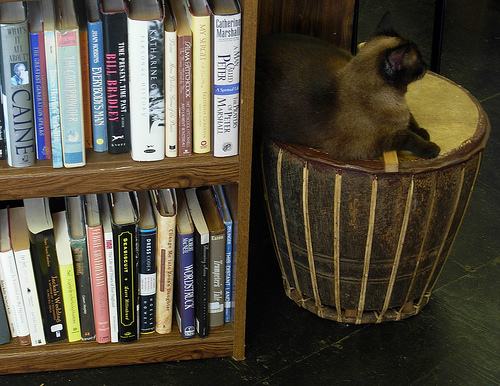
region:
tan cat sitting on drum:
[257, 13, 442, 160]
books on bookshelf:
[3, 1, 238, 166]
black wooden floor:
[257, 186, 498, 384]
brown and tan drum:
[261, 69, 490, 326]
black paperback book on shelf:
[22, 195, 67, 349]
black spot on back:
[305, 73, 345, 120]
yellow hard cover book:
[191, 7, 214, 158]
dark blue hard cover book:
[172, 211, 196, 345]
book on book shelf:
[211, 3, 236, 157]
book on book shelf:
[196, 188, 224, 328]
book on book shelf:
[175, 207, 197, 339]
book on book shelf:
[151, 189, 175, 332]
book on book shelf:
[136, 192, 156, 334]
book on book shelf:
[107, 190, 139, 342]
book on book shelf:
[97, 195, 119, 345]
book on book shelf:
[83, 196, 108, 342]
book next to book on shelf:
[210, 1, 241, 157]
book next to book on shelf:
[188, 0, 214, 156]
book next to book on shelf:
[9, 202, 45, 345]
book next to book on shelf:
[21, 196, 68, 342]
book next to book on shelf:
[54, 209, 80, 342]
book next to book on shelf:
[66, 192, 95, 340]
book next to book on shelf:
[81, 193, 111, 344]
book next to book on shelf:
[98, 191, 119, 341]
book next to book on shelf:
[108, 191, 142, 345]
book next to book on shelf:
[136, 188, 155, 334]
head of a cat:
[365, 28, 430, 95]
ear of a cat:
[395, 43, 426, 70]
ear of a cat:
[374, 10, 404, 46]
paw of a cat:
[417, 135, 444, 163]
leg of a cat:
[374, 125, 437, 159]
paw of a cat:
[412, 120, 437, 136]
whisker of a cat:
[427, 56, 443, 76]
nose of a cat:
[421, 58, 440, 73]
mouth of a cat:
[412, 66, 433, 83]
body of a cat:
[254, 40, 378, 154]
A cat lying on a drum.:
[253, 12, 435, 159]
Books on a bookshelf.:
[1, 182, 238, 346]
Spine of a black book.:
[117, 226, 137, 343]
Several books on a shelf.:
[0, 0, 240, 180]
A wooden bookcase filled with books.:
[2, 3, 245, 380]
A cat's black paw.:
[413, 133, 439, 160]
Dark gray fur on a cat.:
[271, 61, 320, 108]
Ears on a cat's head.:
[372, 8, 404, 78]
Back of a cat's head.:
[358, 10, 428, 85]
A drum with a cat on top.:
[262, 50, 492, 323]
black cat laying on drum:
[268, 17, 488, 325]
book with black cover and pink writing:
[99, 3, 131, 153]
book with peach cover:
[83, 217, 110, 343]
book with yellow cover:
[192, 10, 212, 152]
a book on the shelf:
[162, 220, 235, 315]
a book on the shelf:
[195, 229, 237, 318]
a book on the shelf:
[141, 201, 188, 309]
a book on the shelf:
[108, 222, 154, 312]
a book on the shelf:
[86, 235, 132, 322]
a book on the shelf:
[67, 233, 87, 325]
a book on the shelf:
[50, 237, 79, 339]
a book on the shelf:
[18, 221, 65, 341]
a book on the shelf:
[191, 6, 232, 145]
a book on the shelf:
[54, 40, 92, 172]